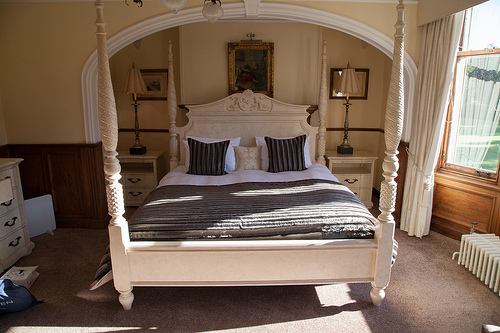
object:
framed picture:
[227, 32, 277, 98]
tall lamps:
[334, 60, 359, 154]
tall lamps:
[126, 61, 149, 155]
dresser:
[0, 156, 37, 274]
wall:
[145, 16, 362, 121]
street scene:
[38, 224, 433, 327]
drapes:
[399, 10, 464, 238]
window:
[464, 14, 498, 174]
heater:
[450, 222, 499, 300]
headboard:
[175, 87, 321, 168]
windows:
[436, 51, 499, 185]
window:
[457, 0, 499, 52]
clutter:
[1, 278, 44, 315]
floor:
[0, 165, 498, 328]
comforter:
[87, 161, 399, 290]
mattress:
[131, 161, 376, 239]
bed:
[93, 0, 409, 310]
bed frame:
[92, 0, 406, 309]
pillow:
[263, 134, 308, 173]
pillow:
[181, 135, 241, 170]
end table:
[324, 148, 380, 208]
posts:
[368, 1, 407, 307]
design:
[223, 95, 276, 111]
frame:
[226, 32, 276, 98]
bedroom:
[6, 4, 484, 299]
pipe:
[457, 232, 497, 265]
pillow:
[255, 134, 312, 170]